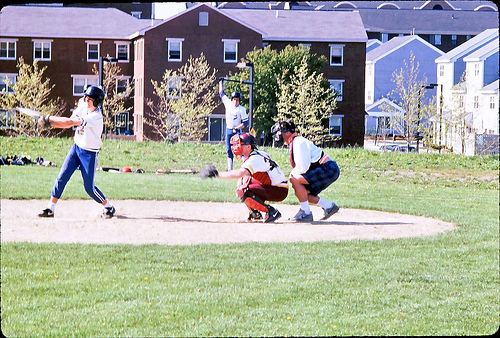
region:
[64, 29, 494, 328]
kids playing facebook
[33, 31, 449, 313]
young kidds playing baseball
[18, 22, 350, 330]
kids playing baseball on a field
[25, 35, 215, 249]
a kid batting on field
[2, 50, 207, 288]
kid swinging a bat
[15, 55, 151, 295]
a child swinging a bat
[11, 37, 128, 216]
a child holding a bat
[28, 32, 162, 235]
a child wearing a helmet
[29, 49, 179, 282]
a child wearing a black helmet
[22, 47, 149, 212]
a kid wearing a helmet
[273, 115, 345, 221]
umpire in checkered black and blue shorts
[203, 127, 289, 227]
catcher in red helmet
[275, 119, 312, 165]
umpire in black helmet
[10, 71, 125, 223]
batter in white shirt and blue pants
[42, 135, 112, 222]
blue pants with white side stripes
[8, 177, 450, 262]
patch of sand in pitcher's mound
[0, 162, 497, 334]
green grass surrounds pitcher's mound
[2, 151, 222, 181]
balls and baseball supplies in back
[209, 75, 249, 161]
another player in the background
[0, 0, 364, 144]
red brick building complex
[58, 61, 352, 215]
people playing a game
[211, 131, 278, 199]
catcher behind the plate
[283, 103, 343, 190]
umpire behind the catcher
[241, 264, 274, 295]
green grass next to catcher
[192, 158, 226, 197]
glove of the catcher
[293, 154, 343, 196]
shorts of the umpire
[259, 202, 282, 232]
shoes of the catcher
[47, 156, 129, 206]
pants of the batter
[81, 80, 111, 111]
helmet on the batter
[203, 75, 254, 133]
person in the background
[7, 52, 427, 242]
The people are playing baseball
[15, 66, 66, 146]
The boy is swinging a baseball bat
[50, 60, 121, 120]
The batter is wearing a helmet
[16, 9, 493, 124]
The background is lined by houses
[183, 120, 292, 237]
The catcher is wearing a mitt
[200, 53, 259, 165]
The man on deck is holding a bat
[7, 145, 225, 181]
The ground is covered with baseball supplies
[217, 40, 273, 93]
The light in the background is on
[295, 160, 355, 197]
The umpire is wearing blue and black checkered shorts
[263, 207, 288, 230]
The catcher is wearing Nike cleats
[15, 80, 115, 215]
boy swinging baseball bat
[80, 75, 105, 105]
black baseball helmet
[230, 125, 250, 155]
red catcher's mask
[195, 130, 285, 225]
catcher squating behind batter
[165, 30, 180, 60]
window in back of house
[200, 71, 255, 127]
boy swinging baseball bat over his head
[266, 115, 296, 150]
black catcher's mask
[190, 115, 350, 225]
two boys playing baseball in field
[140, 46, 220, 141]
white tree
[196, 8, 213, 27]
attic vent on house